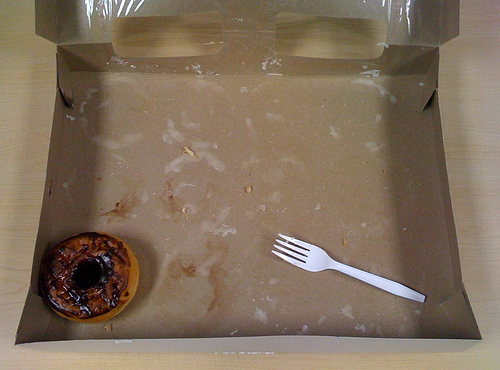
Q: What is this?
A: An almost empty box of doughnuts.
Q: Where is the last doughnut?
A: On the bottom left.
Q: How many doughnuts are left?
A: One.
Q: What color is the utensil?
A: White.